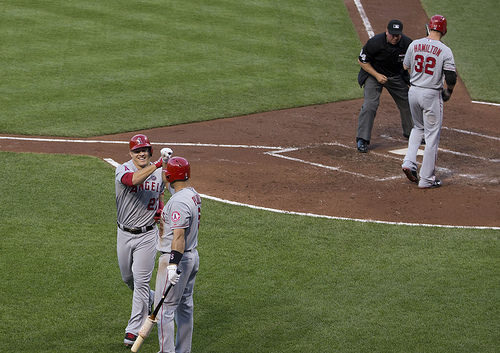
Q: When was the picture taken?
A: When a baseball game was being played.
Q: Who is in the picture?
A: Baseball players and ref.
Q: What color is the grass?
A: Green.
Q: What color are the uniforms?
A: Gray.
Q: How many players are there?
A: 3.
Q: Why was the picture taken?
A: To show the players.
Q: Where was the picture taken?
A: On a baseball field.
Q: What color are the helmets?
A: Red.